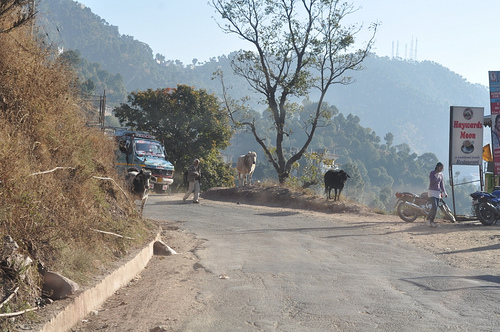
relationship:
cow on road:
[322, 169, 349, 203] [138, 195, 497, 331]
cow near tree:
[322, 169, 349, 203] [218, 0, 378, 187]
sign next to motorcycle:
[448, 105, 484, 221] [396, 185, 458, 225]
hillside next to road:
[7, 2, 139, 273] [138, 195, 497, 331]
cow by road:
[322, 169, 349, 203] [138, 195, 497, 331]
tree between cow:
[218, 0, 378, 187] [322, 169, 349, 203]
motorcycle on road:
[396, 185, 458, 225] [138, 195, 497, 331]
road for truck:
[138, 195, 497, 331] [113, 130, 176, 197]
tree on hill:
[218, 0, 378, 187] [234, 51, 486, 195]